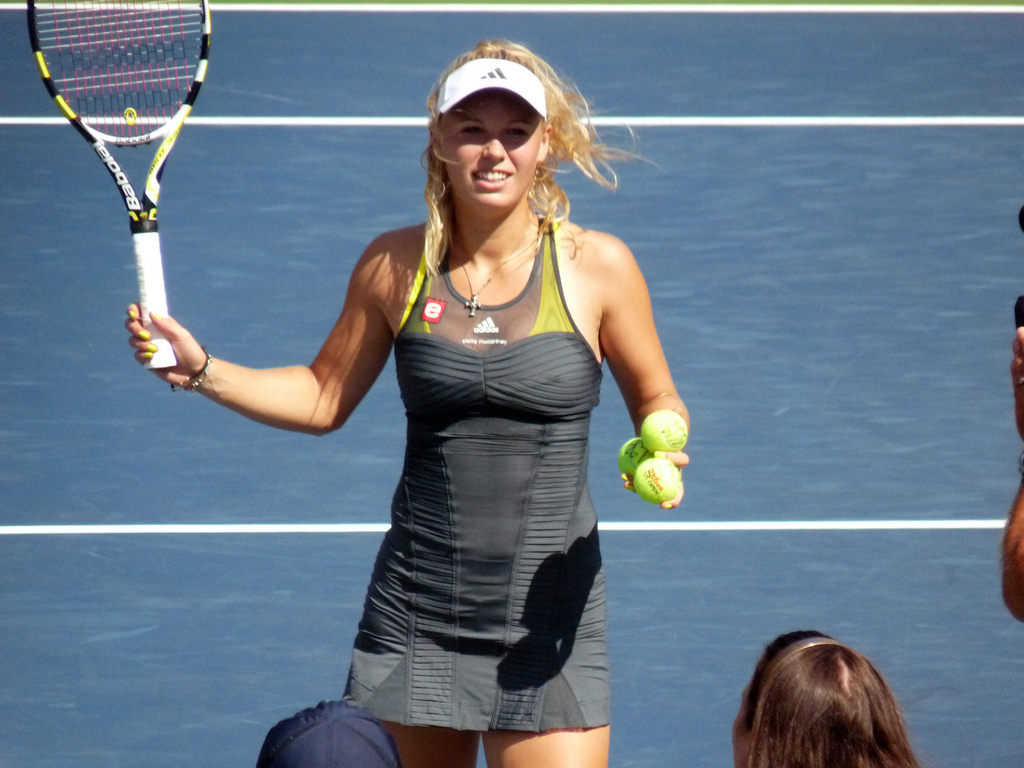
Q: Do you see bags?
A: No, there are no bags.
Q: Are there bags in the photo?
A: No, there are no bags.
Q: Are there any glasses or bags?
A: No, there are no bags or glasses.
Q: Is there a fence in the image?
A: No, there are no fences.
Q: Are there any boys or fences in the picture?
A: No, there are no fences or boys.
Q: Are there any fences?
A: No, there are no fences.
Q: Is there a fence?
A: No, there are no fences.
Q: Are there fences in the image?
A: No, there are no fences.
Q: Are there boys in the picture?
A: No, there are no boys.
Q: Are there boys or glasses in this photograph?
A: No, there are no boys or glasses.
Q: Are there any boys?
A: No, there are no boys.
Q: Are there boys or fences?
A: No, there are no boys or fences.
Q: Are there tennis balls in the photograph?
A: Yes, there is a tennis ball.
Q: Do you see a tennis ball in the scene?
A: Yes, there is a tennis ball.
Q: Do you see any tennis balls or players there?
A: Yes, there is a tennis ball.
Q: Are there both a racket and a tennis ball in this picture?
A: Yes, there are both a tennis ball and a racket.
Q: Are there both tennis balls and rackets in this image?
A: Yes, there are both a tennis ball and a racket.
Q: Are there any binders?
A: No, there are no binders.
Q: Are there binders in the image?
A: No, there are no binders.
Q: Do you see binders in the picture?
A: No, there are no binders.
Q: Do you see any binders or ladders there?
A: No, there are no binders or ladders.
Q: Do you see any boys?
A: No, there are no boys.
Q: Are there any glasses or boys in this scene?
A: No, there are no boys or glasses.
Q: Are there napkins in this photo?
A: No, there are no napkins.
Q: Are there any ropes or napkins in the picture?
A: No, there are no napkins or ropes.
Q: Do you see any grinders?
A: No, there are no grinders.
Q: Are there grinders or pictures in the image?
A: No, there are no grinders or pictures.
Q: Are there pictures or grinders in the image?
A: No, there are no grinders or pictures.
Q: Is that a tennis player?
A: Yes, that is a tennis player.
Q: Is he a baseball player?
A: No, that is a tennis player.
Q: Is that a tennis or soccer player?
A: That is a tennis player.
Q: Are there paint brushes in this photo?
A: No, there are no paint brushes.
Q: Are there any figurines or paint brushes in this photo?
A: No, there are no paint brushes or figurines.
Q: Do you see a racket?
A: Yes, there is a racket.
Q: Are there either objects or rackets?
A: Yes, there is a racket.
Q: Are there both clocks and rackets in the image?
A: No, there is a racket but no clocks.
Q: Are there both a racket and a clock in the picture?
A: No, there is a racket but no clocks.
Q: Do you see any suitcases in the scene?
A: No, there are no suitcases.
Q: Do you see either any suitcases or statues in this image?
A: No, there are no suitcases or statues.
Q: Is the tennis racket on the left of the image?
A: Yes, the tennis racket is on the left of the image.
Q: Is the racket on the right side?
A: No, the racket is on the left of the image.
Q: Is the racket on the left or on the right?
A: The racket is on the left of the image.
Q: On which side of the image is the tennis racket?
A: The tennis racket is on the left of the image.